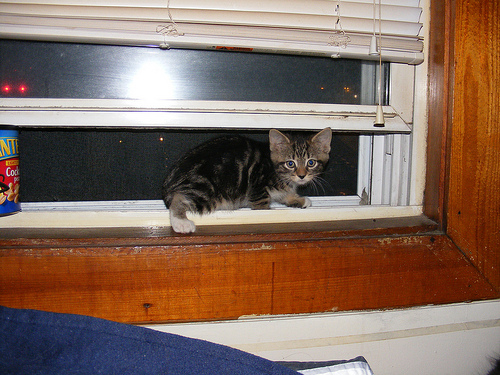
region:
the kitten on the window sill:
[161, 122, 328, 233]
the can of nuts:
[1, 124, 37, 227]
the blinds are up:
[2, 2, 430, 60]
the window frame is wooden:
[16, 245, 495, 321]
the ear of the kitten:
[267, 125, 288, 147]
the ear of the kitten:
[309, 125, 337, 149]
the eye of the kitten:
[280, 155, 297, 171]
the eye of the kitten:
[300, 158, 320, 171]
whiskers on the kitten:
[307, 171, 331, 189]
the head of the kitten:
[256, 120, 350, 196]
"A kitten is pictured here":
[169, 120, 344, 239]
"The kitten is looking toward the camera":
[164, 125, 354, 245]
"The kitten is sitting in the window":
[0, 2, 498, 312]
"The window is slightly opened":
[0, 0, 497, 253]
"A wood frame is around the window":
[0, 0, 497, 321]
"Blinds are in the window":
[6, 0, 450, 232]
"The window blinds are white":
[0, 0, 453, 242]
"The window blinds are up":
[0, 0, 463, 251]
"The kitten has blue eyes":
[255, 99, 348, 210]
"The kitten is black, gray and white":
[152, 114, 350, 252]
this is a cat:
[151, 124, 346, 228]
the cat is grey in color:
[157, 124, 346, 226]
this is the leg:
[169, 193, 196, 236]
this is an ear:
[267, 125, 292, 146]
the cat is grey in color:
[213, 142, 259, 179]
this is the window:
[55, 35, 155, 182]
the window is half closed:
[65, 118, 143, 207]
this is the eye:
[305, 155, 317, 167]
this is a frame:
[338, 231, 415, 303]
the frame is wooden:
[331, 230, 412, 310]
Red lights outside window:
[2, 81, 27, 95]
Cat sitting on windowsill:
[163, 124, 335, 232]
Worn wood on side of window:
[1, 226, 498, 326]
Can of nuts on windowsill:
[0, 130, 21, 215]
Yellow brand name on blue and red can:
[1, 136, 21, 156]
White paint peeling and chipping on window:
[1, 102, 399, 122]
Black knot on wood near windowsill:
[141, 299, 153, 309]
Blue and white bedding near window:
[1, 306, 376, 373]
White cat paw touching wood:
[169, 202, 197, 233]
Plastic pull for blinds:
[368, 35, 385, 125]